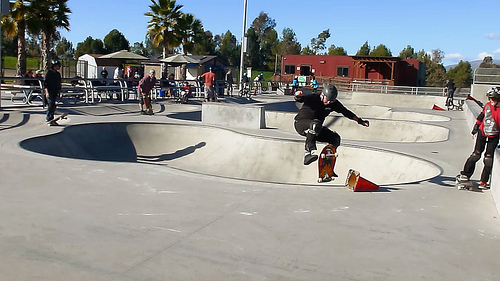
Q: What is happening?
A: Skateboarding.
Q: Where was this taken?
A: A skate park.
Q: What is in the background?
A: A row of trees.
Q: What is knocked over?
A: An orange cone.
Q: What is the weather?
A: Sunny.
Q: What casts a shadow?
A: The skateboarder.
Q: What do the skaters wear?
A: Helmets.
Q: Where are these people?
A: Skate park.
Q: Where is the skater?
A: In the air.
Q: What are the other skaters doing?
A: Watching.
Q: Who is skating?
A: Guy in black.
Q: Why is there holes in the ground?
A: To skate.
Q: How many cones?
A: 2.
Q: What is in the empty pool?
A: The skater.